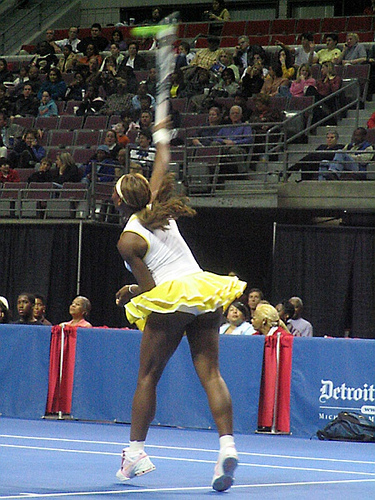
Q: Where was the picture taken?
A: It was taken at the stadium.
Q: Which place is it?
A: It is a stadium.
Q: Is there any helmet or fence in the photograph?
A: No, there are no fences or helmets.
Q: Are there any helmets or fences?
A: No, there are no fences or helmets.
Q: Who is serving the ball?
A: The player is serving the ball.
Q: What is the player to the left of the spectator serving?
A: The player is serving the ball.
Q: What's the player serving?
A: The player is serving the ball.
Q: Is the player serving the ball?
A: Yes, the player is serving the ball.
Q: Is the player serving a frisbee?
A: No, the player is serving the ball.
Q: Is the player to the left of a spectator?
A: Yes, the player is to the left of a spectator.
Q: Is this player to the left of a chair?
A: No, the player is to the left of a spectator.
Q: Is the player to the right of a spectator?
A: No, the player is to the left of a spectator.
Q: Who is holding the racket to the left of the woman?
A: The player is holding the tennis racket.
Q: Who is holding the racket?
A: The player is holding the tennis racket.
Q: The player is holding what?
A: The player is holding the tennis racket.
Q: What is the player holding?
A: The player is holding the tennis racket.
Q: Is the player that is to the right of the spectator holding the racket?
A: Yes, the player is holding the racket.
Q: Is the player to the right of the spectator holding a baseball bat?
A: No, the player is holding the racket.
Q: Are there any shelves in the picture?
A: No, there are no shelves.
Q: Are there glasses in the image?
A: No, there are no glasses.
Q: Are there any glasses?
A: No, there are no glasses.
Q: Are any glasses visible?
A: No, there are no glasses.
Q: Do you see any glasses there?
A: No, there are no glasses.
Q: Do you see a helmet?
A: No, there are no helmets.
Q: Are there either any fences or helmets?
A: No, there are no helmets or fences.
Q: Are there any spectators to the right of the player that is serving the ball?
A: Yes, there is a spectator to the right of the player.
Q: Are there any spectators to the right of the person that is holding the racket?
A: Yes, there is a spectator to the right of the player.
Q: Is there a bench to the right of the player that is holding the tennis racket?
A: No, there is a spectator to the right of the player.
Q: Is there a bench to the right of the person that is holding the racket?
A: No, there is a spectator to the right of the player.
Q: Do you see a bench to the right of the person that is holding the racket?
A: No, there is a spectator to the right of the player.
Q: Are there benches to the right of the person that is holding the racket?
A: No, there is a spectator to the right of the player.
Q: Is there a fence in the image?
A: No, there are no fences.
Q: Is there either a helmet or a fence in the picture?
A: No, there are no fences or helmets.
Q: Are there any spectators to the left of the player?
A: Yes, there is a spectator to the left of the player.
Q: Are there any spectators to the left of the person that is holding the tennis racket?
A: Yes, there is a spectator to the left of the player.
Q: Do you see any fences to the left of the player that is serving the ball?
A: No, there is a spectator to the left of the player.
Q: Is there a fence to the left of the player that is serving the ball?
A: No, there is a spectator to the left of the player.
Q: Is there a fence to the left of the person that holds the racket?
A: No, there is a spectator to the left of the player.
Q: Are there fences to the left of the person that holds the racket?
A: No, there is a spectator to the left of the player.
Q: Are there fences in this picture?
A: No, there are no fences.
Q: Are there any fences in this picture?
A: No, there are no fences.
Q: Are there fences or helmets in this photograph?
A: No, there are no fences or helmets.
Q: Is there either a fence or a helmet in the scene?
A: No, there are no fences or helmets.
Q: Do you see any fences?
A: No, there are no fences.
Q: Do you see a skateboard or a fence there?
A: No, there are no fences or skateboards.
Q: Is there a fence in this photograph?
A: No, there are no fences.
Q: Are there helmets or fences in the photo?
A: No, there are no fences or helmets.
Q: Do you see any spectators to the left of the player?
A: Yes, there is a spectator to the left of the player.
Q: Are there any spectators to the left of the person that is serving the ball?
A: Yes, there is a spectator to the left of the player.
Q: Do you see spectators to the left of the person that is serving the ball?
A: Yes, there is a spectator to the left of the player.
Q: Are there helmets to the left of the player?
A: No, there is a spectator to the left of the player.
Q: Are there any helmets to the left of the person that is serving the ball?
A: No, there is a spectator to the left of the player.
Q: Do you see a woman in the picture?
A: Yes, there is a woman.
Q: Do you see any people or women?
A: Yes, there is a woman.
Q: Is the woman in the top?
A: Yes, the woman is in the top of the image.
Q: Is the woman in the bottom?
A: No, the woman is in the top of the image.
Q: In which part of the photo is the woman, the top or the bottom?
A: The woman is in the top of the image.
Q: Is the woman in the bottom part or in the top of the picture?
A: The woman is in the top of the image.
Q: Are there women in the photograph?
A: Yes, there is a woman.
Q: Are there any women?
A: Yes, there is a woman.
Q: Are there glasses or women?
A: Yes, there is a woman.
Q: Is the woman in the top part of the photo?
A: Yes, the woman is in the top of the image.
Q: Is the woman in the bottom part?
A: No, the woman is in the top of the image.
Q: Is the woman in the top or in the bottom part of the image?
A: The woman is in the top of the image.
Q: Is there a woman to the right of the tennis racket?
A: Yes, there is a woman to the right of the tennis racket.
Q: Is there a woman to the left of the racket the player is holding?
A: No, the woman is to the right of the racket.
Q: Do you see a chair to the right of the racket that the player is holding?
A: No, there is a woman to the right of the tennis racket.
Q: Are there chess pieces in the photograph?
A: No, there are no chess pieces.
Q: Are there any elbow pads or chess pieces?
A: No, there are no chess pieces or elbow pads.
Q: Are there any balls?
A: Yes, there is a ball.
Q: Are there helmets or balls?
A: Yes, there is a ball.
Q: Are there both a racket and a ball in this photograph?
A: Yes, there are both a ball and a racket.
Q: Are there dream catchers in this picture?
A: No, there are no dream catchers.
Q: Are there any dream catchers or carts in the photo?
A: No, there are no dream catchers or carts.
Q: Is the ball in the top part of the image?
A: Yes, the ball is in the top of the image.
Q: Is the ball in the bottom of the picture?
A: No, the ball is in the top of the image.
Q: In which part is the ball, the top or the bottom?
A: The ball is in the top of the image.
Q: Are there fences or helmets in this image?
A: No, there are no helmets or fences.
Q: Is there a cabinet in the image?
A: No, there are no cabinets.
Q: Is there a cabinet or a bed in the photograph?
A: No, there are no cabinets or beds.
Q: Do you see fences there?
A: No, there are no fences.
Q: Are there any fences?
A: No, there are no fences.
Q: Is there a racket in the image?
A: Yes, there is a racket.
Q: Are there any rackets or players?
A: Yes, there is a racket.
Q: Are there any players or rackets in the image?
A: Yes, there is a racket.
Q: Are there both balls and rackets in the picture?
A: Yes, there are both a racket and a ball.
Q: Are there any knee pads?
A: No, there are no knee pads.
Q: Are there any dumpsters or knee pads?
A: No, there are no knee pads or dumpsters.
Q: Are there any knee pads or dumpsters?
A: No, there are no knee pads or dumpsters.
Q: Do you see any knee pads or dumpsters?
A: No, there are no knee pads or dumpsters.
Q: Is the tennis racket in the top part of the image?
A: Yes, the tennis racket is in the top of the image.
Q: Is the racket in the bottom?
A: No, the racket is in the top of the image.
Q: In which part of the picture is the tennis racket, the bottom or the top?
A: The tennis racket is in the top of the image.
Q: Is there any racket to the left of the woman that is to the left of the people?
A: Yes, there is a racket to the left of the woman.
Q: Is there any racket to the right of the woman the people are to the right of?
A: No, the racket is to the left of the woman.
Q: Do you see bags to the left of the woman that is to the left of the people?
A: No, there is a racket to the left of the woman.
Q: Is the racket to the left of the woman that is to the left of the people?
A: Yes, the racket is to the left of the woman.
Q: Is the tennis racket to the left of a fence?
A: No, the tennis racket is to the left of the woman.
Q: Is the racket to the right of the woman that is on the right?
A: No, the racket is to the left of the woman.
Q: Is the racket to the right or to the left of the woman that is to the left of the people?
A: The racket is to the left of the woman.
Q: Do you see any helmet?
A: No, there are no helmets.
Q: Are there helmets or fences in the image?
A: No, there are no helmets or fences.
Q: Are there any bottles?
A: No, there are no bottles.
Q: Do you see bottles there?
A: No, there are no bottles.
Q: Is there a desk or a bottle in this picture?
A: No, there are no bottles or desks.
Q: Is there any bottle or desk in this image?
A: No, there are no bottles or desks.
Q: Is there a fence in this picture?
A: No, there are no fences.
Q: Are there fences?
A: No, there are no fences.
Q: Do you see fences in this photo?
A: No, there are no fences.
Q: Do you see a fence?
A: No, there are no fences.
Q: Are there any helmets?
A: No, there are no helmets.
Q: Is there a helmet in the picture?
A: No, there are no helmets.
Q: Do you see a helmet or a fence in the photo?
A: No, there are no helmets or fences.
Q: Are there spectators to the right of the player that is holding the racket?
A: Yes, there is a spectator to the right of the player.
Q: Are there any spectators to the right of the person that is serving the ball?
A: Yes, there is a spectator to the right of the player.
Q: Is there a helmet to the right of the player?
A: No, there is a spectator to the right of the player.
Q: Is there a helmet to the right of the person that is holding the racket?
A: No, there is a spectator to the right of the player.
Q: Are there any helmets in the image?
A: No, there are no helmets.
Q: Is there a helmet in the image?
A: No, there are no helmets.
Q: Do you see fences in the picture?
A: No, there are no fences.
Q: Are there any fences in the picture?
A: No, there are no fences.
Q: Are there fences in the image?
A: No, there are no fences.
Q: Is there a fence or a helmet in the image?
A: No, there are no fences or helmets.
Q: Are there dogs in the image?
A: No, there are no dogs.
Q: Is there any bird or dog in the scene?
A: No, there are no dogs or birds.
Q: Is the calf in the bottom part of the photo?
A: Yes, the calf is in the bottom of the image.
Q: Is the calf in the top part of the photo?
A: No, the calf is in the bottom of the image.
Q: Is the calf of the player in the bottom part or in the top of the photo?
A: The calf is in the bottom of the image.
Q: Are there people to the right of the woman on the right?
A: Yes, there are people to the right of the woman.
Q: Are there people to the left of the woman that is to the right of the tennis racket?
A: No, the people are to the right of the woman.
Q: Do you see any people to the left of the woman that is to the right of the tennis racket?
A: No, the people are to the right of the woman.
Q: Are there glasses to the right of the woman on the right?
A: No, there are people to the right of the woman.